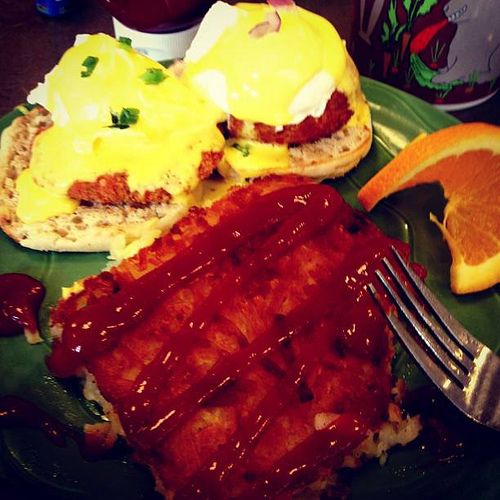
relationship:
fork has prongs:
[365, 242, 499, 432] [365, 243, 472, 386]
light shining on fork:
[464, 347, 491, 405] [365, 242, 499, 432]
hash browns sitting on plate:
[62, 184, 411, 499] [0, 74, 498, 498]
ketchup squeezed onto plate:
[0, 272, 47, 333] [0, 74, 498, 498]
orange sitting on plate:
[358, 120, 499, 294] [0, 74, 498, 498]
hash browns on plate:
[62, 184, 411, 499] [0, 74, 498, 498]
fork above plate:
[365, 242, 499, 432] [0, 74, 498, 498]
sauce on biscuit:
[50, 6, 370, 215] [0, 114, 204, 256]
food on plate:
[0, 3, 500, 497] [0, 74, 498, 498]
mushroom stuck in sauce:
[248, 11, 282, 39] [50, 6, 370, 215]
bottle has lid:
[109, 0, 208, 62] [111, 17, 200, 64]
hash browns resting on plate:
[62, 184, 411, 499] [0, 74, 498, 498]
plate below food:
[0, 74, 498, 498] [0, 3, 500, 497]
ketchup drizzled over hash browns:
[62, 184, 411, 499] [62, 184, 411, 499]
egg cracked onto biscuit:
[185, 1, 340, 122] [0, 114, 204, 256]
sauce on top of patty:
[50, 6, 370, 215] [226, 91, 353, 144]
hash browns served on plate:
[62, 184, 411, 499] [0, 74, 498, 498]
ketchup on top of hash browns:
[62, 184, 411, 499] [62, 184, 411, 499]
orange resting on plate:
[358, 120, 499, 294] [0, 74, 498, 498]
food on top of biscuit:
[0, 3, 500, 497] [0, 114, 204, 256]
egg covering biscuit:
[185, 1, 340, 122] [0, 114, 204, 256]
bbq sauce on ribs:
[228, 292, 284, 345] [106, 274, 383, 405]